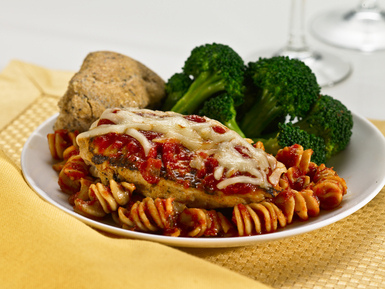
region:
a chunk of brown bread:
[54, 49, 166, 129]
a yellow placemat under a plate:
[1, 57, 383, 286]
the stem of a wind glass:
[256, 0, 354, 84]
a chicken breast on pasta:
[76, 138, 273, 207]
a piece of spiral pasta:
[233, 188, 320, 233]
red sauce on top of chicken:
[99, 120, 257, 192]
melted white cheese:
[76, 105, 290, 187]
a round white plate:
[23, 99, 384, 249]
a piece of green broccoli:
[171, 42, 244, 110]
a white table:
[1, 1, 384, 118]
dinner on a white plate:
[17, 42, 383, 250]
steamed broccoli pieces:
[172, 40, 355, 162]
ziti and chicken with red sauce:
[59, 105, 342, 238]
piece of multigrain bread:
[51, 42, 163, 122]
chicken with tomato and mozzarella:
[73, 102, 286, 201]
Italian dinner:
[23, 40, 375, 252]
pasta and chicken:
[52, 102, 344, 237]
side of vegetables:
[167, 43, 355, 161]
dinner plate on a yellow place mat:
[2, 42, 382, 287]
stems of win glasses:
[260, 0, 384, 89]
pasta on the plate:
[235, 205, 283, 228]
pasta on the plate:
[193, 209, 221, 235]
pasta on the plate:
[146, 201, 177, 229]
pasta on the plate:
[91, 185, 122, 212]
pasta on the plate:
[281, 190, 313, 218]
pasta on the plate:
[320, 170, 340, 197]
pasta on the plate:
[278, 147, 308, 172]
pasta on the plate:
[59, 156, 75, 182]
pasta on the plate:
[123, 203, 156, 226]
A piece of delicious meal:
[61, 38, 371, 222]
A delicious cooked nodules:
[232, 206, 277, 234]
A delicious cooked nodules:
[125, 196, 174, 231]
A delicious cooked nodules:
[287, 141, 338, 207]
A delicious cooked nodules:
[58, 144, 95, 192]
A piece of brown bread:
[84, 48, 163, 119]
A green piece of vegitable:
[258, 50, 311, 119]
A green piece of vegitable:
[280, 101, 359, 159]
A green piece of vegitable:
[171, 20, 241, 104]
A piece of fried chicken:
[113, 108, 255, 206]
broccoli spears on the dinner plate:
[163, 42, 353, 112]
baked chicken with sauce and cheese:
[78, 107, 290, 205]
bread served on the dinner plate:
[53, 50, 164, 127]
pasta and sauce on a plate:
[117, 198, 299, 235]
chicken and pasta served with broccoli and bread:
[47, 104, 348, 236]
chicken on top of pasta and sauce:
[46, 108, 347, 237]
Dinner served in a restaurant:
[18, 42, 384, 249]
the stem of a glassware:
[282, 0, 310, 48]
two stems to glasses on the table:
[276, 1, 383, 49]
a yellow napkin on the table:
[0, 247, 273, 287]